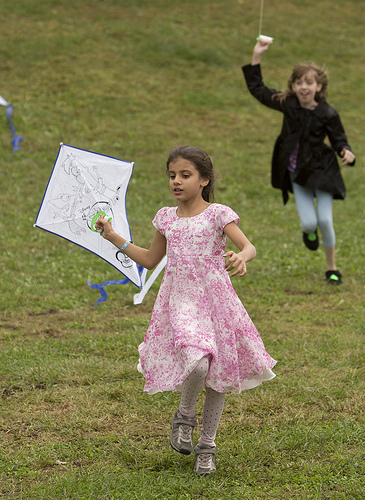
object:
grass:
[265, 285, 362, 339]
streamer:
[87, 253, 168, 306]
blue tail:
[86, 265, 144, 305]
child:
[241, 34, 357, 284]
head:
[290, 60, 328, 104]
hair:
[269, 62, 330, 109]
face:
[169, 160, 198, 201]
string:
[255, 32, 276, 50]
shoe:
[168, 410, 196, 455]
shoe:
[193, 440, 216, 475]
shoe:
[301, 229, 320, 250]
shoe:
[324, 268, 342, 285]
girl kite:
[32, 141, 168, 307]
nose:
[173, 173, 183, 186]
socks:
[178, 356, 226, 446]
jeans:
[292, 180, 337, 247]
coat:
[241, 62, 356, 205]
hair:
[166, 145, 213, 204]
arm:
[112, 207, 168, 271]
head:
[166, 145, 215, 203]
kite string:
[260, 0, 263, 35]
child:
[95, 145, 278, 477]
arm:
[240, 58, 285, 116]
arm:
[326, 108, 351, 147]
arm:
[215, 203, 257, 260]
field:
[0, 0, 365, 498]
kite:
[255, 0, 269, 37]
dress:
[136, 202, 277, 396]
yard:
[0, 0, 365, 499]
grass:
[0, 356, 131, 498]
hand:
[251, 35, 274, 57]